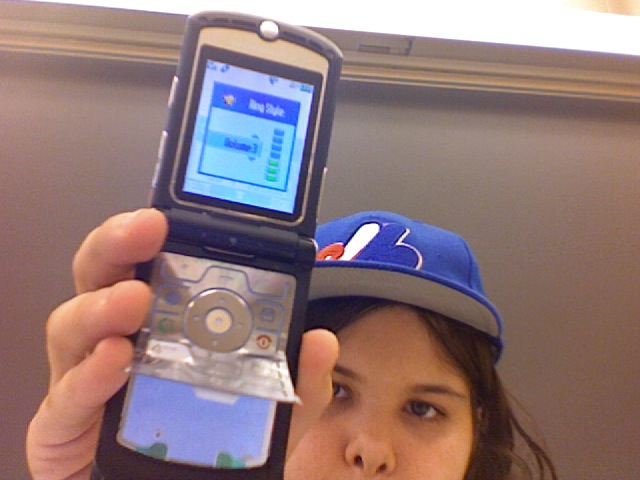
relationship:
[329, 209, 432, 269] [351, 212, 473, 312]
logo on hat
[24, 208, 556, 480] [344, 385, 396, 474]
child has bridge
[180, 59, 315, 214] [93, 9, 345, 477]
screen of cellphone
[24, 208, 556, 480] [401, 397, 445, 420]
child has eye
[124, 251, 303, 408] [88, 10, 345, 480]
keyboard broken on cellphone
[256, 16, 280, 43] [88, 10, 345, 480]
carrier emblem on cellphone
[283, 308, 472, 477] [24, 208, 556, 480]
face of child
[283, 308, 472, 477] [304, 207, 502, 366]
face underneath hat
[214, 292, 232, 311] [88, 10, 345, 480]
arrow on cellphone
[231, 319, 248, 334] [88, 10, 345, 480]
arrow on cellphone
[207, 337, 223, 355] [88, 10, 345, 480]
arrow on cellphone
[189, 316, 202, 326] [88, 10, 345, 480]
arrow on cellphone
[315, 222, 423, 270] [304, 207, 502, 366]
logo on hat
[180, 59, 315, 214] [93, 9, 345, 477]
screen on cellphone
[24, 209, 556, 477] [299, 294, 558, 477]
child has hair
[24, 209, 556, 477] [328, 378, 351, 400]
child has eye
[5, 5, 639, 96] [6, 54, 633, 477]
molding on top of wall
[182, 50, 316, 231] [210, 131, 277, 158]
screen indicates volume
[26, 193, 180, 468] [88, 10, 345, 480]
fingers on left side of cellphone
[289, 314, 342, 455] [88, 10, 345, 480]
thumb on right side of cellphone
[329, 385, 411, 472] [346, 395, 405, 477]
bridge of nose